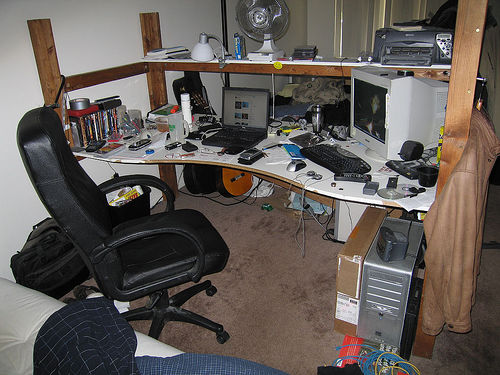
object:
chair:
[17, 107, 231, 344]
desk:
[69, 108, 439, 213]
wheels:
[214, 331, 232, 344]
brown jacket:
[421, 108, 499, 337]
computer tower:
[355, 216, 425, 368]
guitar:
[172, 77, 254, 198]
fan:
[234, 0, 290, 62]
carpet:
[227, 197, 493, 370]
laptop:
[200, 86, 269, 151]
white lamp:
[190, 32, 231, 70]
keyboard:
[297, 142, 373, 177]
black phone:
[171, 76, 215, 117]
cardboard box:
[332, 207, 391, 338]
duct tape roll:
[69, 96, 91, 110]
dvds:
[67, 105, 143, 153]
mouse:
[286, 159, 307, 172]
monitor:
[349, 68, 450, 162]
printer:
[371, 19, 456, 67]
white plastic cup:
[167, 113, 190, 143]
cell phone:
[164, 139, 184, 151]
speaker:
[398, 140, 425, 162]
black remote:
[334, 170, 371, 183]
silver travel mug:
[311, 104, 321, 133]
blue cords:
[331, 340, 425, 374]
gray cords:
[285, 170, 327, 260]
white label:
[334, 290, 362, 326]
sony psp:
[128, 138, 152, 152]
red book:
[67, 103, 101, 118]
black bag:
[10, 214, 91, 301]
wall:
[8, 7, 220, 292]